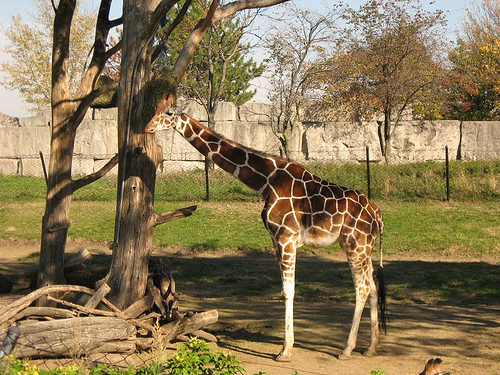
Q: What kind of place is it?
A: It is a forest.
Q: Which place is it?
A: It is a forest.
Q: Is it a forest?
A: Yes, it is a forest.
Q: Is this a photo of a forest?
A: Yes, it is showing a forest.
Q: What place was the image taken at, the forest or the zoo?
A: It was taken at the forest.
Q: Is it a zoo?
A: No, it is a forest.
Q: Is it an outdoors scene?
A: Yes, it is outdoors.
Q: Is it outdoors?
A: Yes, it is outdoors.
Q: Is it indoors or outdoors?
A: It is outdoors.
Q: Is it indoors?
A: No, it is outdoors.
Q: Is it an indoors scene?
A: No, it is outdoors.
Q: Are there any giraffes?
A: Yes, there is a giraffe.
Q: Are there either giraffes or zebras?
A: Yes, there is a giraffe.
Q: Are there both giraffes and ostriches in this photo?
A: No, there is a giraffe but no ostriches.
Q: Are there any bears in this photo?
A: No, there are no bears.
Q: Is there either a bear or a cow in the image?
A: No, there are no bears or cows.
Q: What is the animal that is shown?
A: The animal is a giraffe.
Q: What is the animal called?
A: The animal is a giraffe.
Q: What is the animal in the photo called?
A: The animal is a giraffe.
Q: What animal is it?
A: The animal is a giraffe.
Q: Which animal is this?
A: This is a giraffe.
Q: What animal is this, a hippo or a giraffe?
A: This is a giraffe.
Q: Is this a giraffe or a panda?
A: This is a giraffe.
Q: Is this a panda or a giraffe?
A: This is a giraffe.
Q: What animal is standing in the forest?
A: The giraffe is standing in the forest.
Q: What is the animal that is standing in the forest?
A: The animal is a giraffe.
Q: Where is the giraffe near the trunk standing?
A: The giraffe is standing in the forest.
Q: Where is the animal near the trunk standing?
A: The giraffe is standing in the forest.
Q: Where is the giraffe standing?
A: The giraffe is standing in the forest.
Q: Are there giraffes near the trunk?
A: Yes, there is a giraffe near the trunk.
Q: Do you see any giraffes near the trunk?
A: Yes, there is a giraffe near the trunk.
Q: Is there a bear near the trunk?
A: No, there is a giraffe near the trunk.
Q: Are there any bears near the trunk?
A: No, there is a giraffe near the trunk.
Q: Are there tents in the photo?
A: No, there are no tents.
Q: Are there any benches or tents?
A: No, there are no tents or benches.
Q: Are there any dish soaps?
A: No, there are no dish soaps.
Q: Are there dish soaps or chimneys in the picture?
A: No, there are no dish soaps or chimneys.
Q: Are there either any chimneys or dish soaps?
A: No, there are no dish soaps or chimneys.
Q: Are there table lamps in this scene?
A: No, there are no table lamps.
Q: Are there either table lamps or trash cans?
A: No, there are no table lamps or trash cans.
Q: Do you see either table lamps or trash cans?
A: No, there are no table lamps or trash cans.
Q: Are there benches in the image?
A: No, there are no benches.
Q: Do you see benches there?
A: No, there are no benches.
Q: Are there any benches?
A: No, there are no benches.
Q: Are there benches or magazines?
A: No, there are no benches or magazines.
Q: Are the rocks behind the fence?
A: Yes, the rocks are behind the fence.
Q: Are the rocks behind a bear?
A: No, the rocks are behind the fence.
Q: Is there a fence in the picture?
A: Yes, there is a fence.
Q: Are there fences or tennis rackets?
A: Yes, there is a fence.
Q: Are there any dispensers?
A: No, there are no dispensers.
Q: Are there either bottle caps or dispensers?
A: No, there are no dispensers or bottle caps.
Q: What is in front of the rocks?
A: The fence is in front of the rocks.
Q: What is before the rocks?
A: The fence is in front of the rocks.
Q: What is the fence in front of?
A: The fence is in front of the rocks.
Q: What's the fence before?
A: The fence is in front of the rocks.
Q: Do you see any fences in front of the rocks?
A: Yes, there is a fence in front of the rocks.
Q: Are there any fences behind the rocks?
A: No, the fence is in front of the rocks.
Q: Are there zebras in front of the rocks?
A: No, there is a fence in front of the rocks.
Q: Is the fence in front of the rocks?
A: Yes, the fence is in front of the rocks.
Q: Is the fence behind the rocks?
A: No, the fence is in front of the rocks.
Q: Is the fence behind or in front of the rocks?
A: The fence is in front of the rocks.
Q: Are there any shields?
A: No, there are no shields.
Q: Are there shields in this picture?
A: No, there are no shields.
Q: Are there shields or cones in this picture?
A: No, there are no shields or cones.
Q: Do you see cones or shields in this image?
A: No, there are no shields or cones.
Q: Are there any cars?
A: No, there are no cars.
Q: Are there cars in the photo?
A: No, there are no cars.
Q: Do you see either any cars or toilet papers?
A: No, there are no cars or toilet papers.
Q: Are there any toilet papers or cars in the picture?
A: No, there are no cars or toilet papers.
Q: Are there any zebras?
A: No, there are no zebras.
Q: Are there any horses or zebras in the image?
A: No, there are no zebras or horses.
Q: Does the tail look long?
A: Yes, the tail is long.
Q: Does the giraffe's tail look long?
A: Yes, the tail is long.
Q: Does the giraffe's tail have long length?
A: Yes, the tail is long.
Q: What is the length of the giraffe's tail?
A: The tail is long.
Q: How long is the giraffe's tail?
A: The tail is long.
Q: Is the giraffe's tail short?
A: No, the tail is long.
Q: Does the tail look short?
A: No, the tail is long.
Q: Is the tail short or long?
A: The tail is long.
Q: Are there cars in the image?
A: No, there are no cars.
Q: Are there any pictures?
A: No, there are no pictures.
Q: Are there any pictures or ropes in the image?
A: No, there are no pictures or ropes.